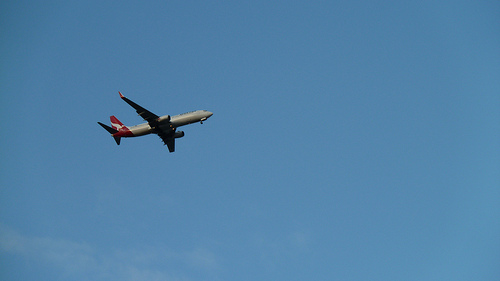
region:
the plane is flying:
[72, 58, 219, 174]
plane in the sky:
[63, 72, 215, 154]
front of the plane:
[182, 100, 218, 125]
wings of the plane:
[111, 85, 163, 125]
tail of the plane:
[100, 108, 127, 128]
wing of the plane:
[163, 133, 183, 152]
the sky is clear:
[361, 88, 463, 213]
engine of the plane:
[175, 130, 188, 136]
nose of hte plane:
[207, 112, 212, 117]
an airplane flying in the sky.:
[95, 91, 214, 158]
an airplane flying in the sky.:
[95, 90, 211, 152]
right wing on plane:
[114, 89, 160, 117]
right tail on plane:
[98, 117, 117, 131]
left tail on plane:
[113, 132, 128, 148]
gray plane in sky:
[76, 63, 233, 158]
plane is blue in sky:
[86, 73, 234, 156]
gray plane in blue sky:
[84, 86, 258, 160]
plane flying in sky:
[81, 76, 226, 166]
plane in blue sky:
[85, 77, 257, 160]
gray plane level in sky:
[85, 74, 257, 151]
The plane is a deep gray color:
[183, 95, 211, 148]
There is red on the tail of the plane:
[104, 116, 124, 158]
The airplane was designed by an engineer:
[78, 31, 285, 258]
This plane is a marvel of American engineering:
[85, 54, 292, 269]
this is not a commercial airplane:
[123, 73, 271, 265]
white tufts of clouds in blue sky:
[1, 229, 311, 278]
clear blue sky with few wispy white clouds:
[1, 2, 498, 277]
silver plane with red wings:
[95, 91, 213, 155]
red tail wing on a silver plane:
[108, 114, 130, 136]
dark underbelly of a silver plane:
[118, 91, 185, 154]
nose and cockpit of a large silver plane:
[195, 105, 214, 127]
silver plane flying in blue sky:
[98, 89, 215, 155]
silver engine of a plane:
[156, 114, 169, 124]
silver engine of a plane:
[173, 128, 183, 139]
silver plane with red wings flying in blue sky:
[95, 89, 217, 157]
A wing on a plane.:
[118, 90, 158, 124]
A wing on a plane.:
[161, 127, 184, 159]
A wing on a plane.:
[94, 121, 109, 135]